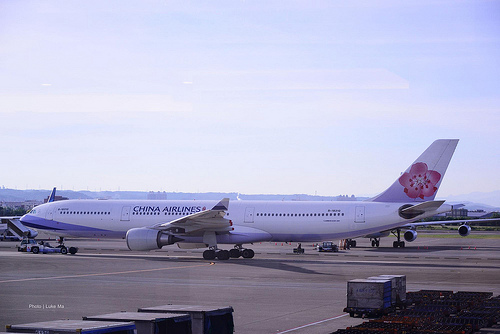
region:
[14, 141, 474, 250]
an airplane at the airport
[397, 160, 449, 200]
a pink flower on the tail of an airplane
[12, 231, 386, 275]
wheels underneath the airplane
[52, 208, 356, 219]
windows on the airplane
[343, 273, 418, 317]
gray and blue cargo boxes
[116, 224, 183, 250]
an engine on the wing of the plane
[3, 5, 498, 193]
a blue sky with clouds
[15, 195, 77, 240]
blue and white nose of the airplane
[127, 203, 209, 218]
logo on the side of the plane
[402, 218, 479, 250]
two engines on a plane's wing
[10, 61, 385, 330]
an airplane on the ground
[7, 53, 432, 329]
a plane on the ground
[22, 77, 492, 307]
an large airplane on the ground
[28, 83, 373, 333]
a large plane on the ground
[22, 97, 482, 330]
a large airplane on the ground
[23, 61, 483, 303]
a white airplane on the ground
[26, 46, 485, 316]
a white plane on the ground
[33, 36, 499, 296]
a passenger airplane on the ground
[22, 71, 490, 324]
a passenger plane on the ground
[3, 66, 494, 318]
a white passenger plane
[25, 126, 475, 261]
chine airlines passenger jet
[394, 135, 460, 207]
airplane tail with sakura blossom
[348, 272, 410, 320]
rolling carts for loading and unloading luggage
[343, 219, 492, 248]
wing and wheels from plane behind formost jet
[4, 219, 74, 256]
stairs for airplanes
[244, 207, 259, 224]
rear emergency door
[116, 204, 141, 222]
front door for loading and unloading passengers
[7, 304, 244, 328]
more carts for luggage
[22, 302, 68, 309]
small white letters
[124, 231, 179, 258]
engine attached to wing of plane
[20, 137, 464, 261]
the airplane on the tarmac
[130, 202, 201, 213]
the words CHINA AIRLINES on the plane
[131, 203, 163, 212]
the word CHINA on the plane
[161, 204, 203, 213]
the word AIRLINES on the side of the plane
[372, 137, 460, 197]
the tail on the plane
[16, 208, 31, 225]
the nose of the plane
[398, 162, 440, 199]
the flower on the tail of the plane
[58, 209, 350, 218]
the windows for the passengers on the side of the plane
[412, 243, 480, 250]
the cones on the tarmac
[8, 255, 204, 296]
the line on the tarmac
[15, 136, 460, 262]
a super jet is on the tarmac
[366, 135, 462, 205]
the tail has a flower on it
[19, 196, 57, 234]
the cockpit of the jet is near the nose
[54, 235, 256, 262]
the landing gear is under the jet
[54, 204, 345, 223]
the windows are along the fuselage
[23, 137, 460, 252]
the plane is a passenger jet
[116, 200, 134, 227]
a door is on the side of the fuselage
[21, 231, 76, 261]
a towing vehicle is near the jet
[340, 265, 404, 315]
luggage carts are on the tarmac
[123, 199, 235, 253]
the jet engine is on the wing